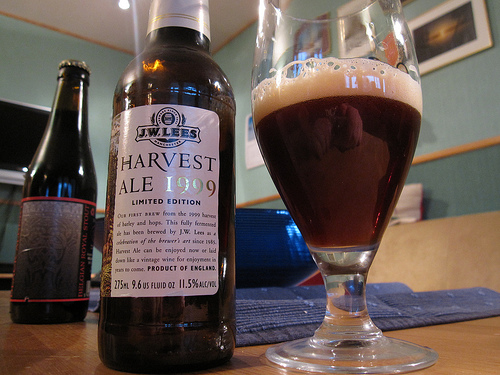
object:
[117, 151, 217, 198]
lettering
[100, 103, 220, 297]
label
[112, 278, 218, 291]
numbers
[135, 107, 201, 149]
logo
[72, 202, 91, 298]
letters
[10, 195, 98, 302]
label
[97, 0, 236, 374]
bottle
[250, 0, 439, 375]
wine glass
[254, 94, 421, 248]
liquid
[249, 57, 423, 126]
bubbles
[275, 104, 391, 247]
reflection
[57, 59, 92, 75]
top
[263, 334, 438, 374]
base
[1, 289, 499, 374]
table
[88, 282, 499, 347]
placemat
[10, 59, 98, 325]
bottle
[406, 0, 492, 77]
photo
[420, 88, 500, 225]
wall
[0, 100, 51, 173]
screen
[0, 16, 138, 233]
wall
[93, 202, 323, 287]
bowl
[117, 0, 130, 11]
light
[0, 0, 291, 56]
ceiling